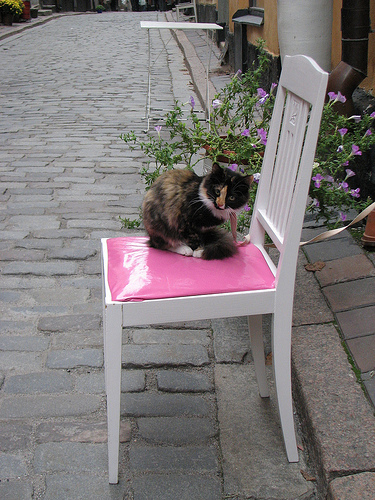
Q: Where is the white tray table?
A: On cobblestones.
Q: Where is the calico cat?
A: On the chair.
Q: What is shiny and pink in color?
A: The chair cushion.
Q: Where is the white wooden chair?
A: On cobblestones.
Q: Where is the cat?
A: On a chair.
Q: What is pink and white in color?
A: The chair.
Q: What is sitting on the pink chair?
A: Cat.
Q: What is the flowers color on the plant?
A: Purple.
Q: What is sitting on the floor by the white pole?
A: Table.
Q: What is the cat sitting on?
A: Chair.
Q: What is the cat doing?
A: Sitting.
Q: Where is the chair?
A: On the street.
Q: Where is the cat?
A: On the chair.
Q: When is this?
A: During the day.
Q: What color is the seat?
A: Pink.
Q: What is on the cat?
A: A leash.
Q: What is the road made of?
A: Cobblestone.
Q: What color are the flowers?
A: Purple.